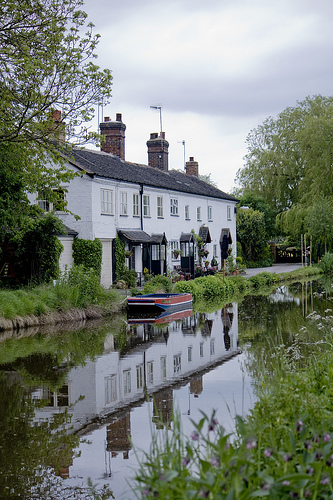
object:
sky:
[0, 0, 333, 198]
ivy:
[113, 234, 139, 289]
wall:
[92, 184, 239, 295]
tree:
[232, 87, 333, 264]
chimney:
[101, 408, 134, 469]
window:
[99, 184, 114, 217]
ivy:
[70, 235, 103, 288]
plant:
[157, 408, 333, 500]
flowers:
[176, 439, 196, 473]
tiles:
[100, 158, 109, 169]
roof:
[44, 135, 240, 204]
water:
[0, 276, 333, 500]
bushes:
[251, 270, 282, 296]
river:
[0, 271, 333, 500]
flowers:
[202, 408, 224, 442]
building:
[23, 294, 242, 474]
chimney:
[185, 154, 199, 178]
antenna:
[177, 140, 187, 171]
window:
[156, 194, 165, 221]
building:
[0, 109, 241, 294]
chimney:
[97, 109, 128, 161]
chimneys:
[144, 127, 170, 176]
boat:
[124, 290, 194, 319]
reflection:
[26, 290, 259, 491]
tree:
[0, 0, 118, 270]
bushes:
[174, 279, 205, 313]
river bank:
[0, 260, 319, 335]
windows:
[226, 203, 233, 222]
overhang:
[115, 224, 169, 247]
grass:
[0, 304, 110, 332]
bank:
[0, 281, 125, 331]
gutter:
[137, 181, 146, 197]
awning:
[118, 226, 156, 245]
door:
[120, 246, 137, 279]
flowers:
[298, 324, 308, 338]